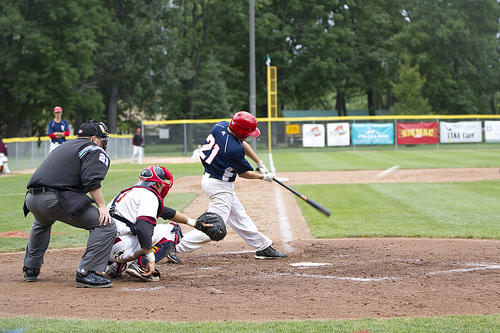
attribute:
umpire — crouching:
[22, 118, 115, 290]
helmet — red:
[227, 105, 263, 139]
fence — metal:
[15, 112, 495, 166]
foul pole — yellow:
[264, 53, 279, 156]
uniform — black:
[24, 134, 111, 272]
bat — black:
[273, 176, 333, 220]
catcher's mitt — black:
[195, 209, 229, 243]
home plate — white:
[290, 256, 331, 272]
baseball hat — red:
[51, 103, 66, 114]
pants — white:
[191, 176, 270, 257]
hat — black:
[77, 119, 96, 136]